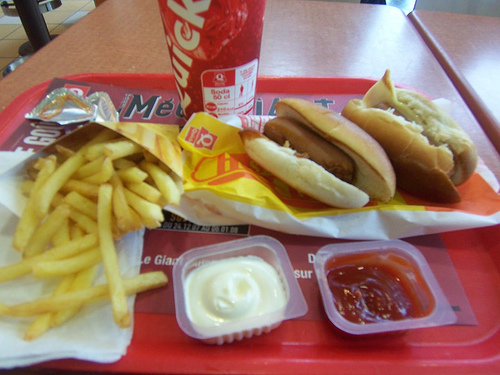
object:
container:
[310, 238, 457, 339]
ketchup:
[359, 271, 399, 303]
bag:
[1, 120, 186, 227]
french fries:
[95, 182, 134, 329]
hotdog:
[260, 115, 358, 187]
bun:
[236, 96, 397, 210]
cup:
[155, 0, 266, 124]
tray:
[2, 70, 499, 375]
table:
[0, 0, 500, 193]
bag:
[162, 110, 499, 241]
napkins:
[0, 149, 147, 364]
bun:
[338, 67, 477, 204]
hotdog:
[371, 100, 457, 180]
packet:
[171, 234, 310, 345]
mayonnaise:
[204, 272, 269, 313]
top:
[23, 86, 99, 127]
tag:
[200, 58, 259, 122]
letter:
[122, 94, 161, 119]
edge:
[18, 72, 100, 103]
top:
[84, 91, 120, 125]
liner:
[2, 76, 481, 331]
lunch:
[0, 269, 171, 318]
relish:
[390, 97, 428, 124]